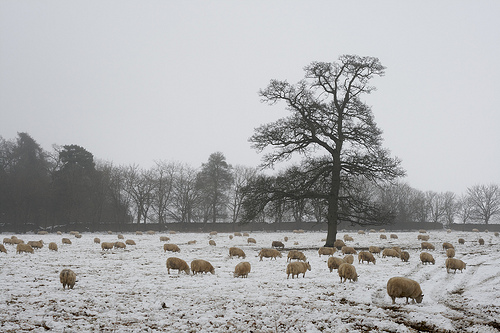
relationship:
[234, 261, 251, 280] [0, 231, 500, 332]
sheep in snow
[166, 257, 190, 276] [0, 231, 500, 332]
sheep in snow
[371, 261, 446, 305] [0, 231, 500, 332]
track in snow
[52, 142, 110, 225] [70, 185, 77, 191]
tree has needles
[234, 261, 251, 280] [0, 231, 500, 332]
sheep dig through snow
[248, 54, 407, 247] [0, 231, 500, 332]
tree in snow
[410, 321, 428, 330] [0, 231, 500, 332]
dirt in snow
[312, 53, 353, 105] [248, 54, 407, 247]
branch of tree